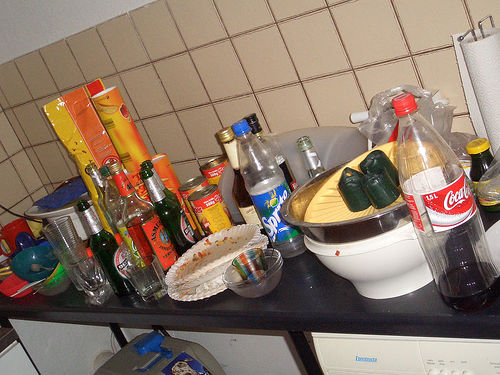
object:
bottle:
[393, 94, 500, 307]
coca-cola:
[443, 182, 478, 209]